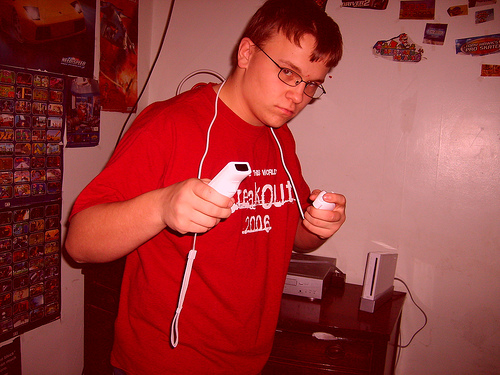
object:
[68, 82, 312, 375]
tshirt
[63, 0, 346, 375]
boy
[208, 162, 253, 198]
controller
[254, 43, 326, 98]
eyeglasses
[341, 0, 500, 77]
stickers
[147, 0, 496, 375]
wall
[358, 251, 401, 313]
wii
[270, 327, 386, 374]
drawer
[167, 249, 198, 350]
strap